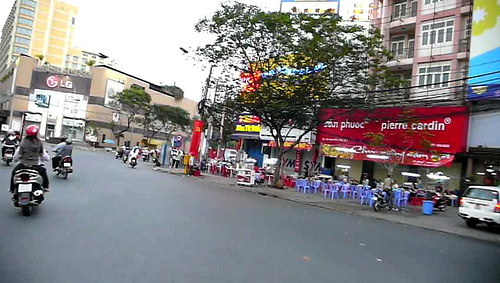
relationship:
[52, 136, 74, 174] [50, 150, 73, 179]
person riding bikes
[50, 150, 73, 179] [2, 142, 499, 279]
bikes on road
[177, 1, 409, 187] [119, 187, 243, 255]
tree near road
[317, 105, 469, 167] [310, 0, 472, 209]
banner hanging from building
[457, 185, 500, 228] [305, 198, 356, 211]
car on sidewak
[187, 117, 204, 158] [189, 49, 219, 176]
sign attached to pole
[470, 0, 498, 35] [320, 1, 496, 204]
flower on building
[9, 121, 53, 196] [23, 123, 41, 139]
girl has helmet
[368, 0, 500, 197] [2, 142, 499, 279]
building on road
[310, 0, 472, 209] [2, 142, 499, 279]
building on road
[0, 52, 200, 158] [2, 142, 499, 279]
building on road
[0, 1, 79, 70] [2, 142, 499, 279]
building on road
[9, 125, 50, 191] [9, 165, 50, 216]
girl on bike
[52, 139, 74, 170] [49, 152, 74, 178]
person on motorcycle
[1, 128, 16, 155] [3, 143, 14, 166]
person on motorcycle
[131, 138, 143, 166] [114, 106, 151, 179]
person on motorcycle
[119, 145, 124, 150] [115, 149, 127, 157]
person on motorcycle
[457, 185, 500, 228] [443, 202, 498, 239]
car in driveway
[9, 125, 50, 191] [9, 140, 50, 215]
girl on bike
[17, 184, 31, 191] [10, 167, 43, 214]
license plate on bike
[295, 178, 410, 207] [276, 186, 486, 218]
blue chair on sidewalk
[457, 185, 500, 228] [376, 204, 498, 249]
car on drive way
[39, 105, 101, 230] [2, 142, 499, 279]
bikes on road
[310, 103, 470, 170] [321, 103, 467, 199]
covering over store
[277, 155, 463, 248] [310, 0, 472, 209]
sidewalk in front of building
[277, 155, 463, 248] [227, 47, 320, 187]
sidewalk in front of building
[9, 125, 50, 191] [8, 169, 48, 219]
girl riding motorcycle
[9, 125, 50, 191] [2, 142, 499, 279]
girl riding on road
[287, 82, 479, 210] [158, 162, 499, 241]
store on sidewalk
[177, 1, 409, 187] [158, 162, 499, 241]
tree on sidewalk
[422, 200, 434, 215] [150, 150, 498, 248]
bin on sidewalk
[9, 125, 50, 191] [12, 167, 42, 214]
girl on motorcycle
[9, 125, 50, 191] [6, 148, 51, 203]
girl on motorcycle